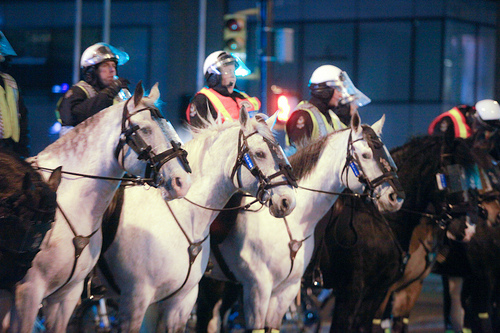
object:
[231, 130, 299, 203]
bridle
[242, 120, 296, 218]
horse face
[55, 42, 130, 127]
officer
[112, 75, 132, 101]
water bottle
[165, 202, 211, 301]
harness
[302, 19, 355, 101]
window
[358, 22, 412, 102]
window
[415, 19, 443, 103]
window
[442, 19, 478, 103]
window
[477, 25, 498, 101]
window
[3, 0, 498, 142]
building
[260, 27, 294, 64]
box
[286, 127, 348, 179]
brown mane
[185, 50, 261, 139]
officer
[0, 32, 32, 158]
officer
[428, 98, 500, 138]
officer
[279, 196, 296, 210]
nose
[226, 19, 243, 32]
light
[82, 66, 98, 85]
head set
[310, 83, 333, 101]
head set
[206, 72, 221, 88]
head set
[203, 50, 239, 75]
helmet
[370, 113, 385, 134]
ear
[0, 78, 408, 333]
three horses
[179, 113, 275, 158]
manes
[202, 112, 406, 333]
horse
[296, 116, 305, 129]
badge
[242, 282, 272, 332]
leg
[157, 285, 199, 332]
leg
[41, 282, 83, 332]
leg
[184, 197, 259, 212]
rope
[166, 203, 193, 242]
rope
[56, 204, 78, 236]
rope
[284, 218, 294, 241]
rope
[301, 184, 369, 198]
rope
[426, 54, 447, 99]
wall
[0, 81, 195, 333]
horses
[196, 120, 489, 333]
horses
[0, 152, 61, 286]
horses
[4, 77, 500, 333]
row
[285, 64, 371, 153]
officer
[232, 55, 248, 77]
light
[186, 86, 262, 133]
vest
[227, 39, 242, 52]
light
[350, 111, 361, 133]
ear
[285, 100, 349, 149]
vest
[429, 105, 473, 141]
safety jacket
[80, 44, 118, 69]
helmet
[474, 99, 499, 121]
helmet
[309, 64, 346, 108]
head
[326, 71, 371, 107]
helmet shield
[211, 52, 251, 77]
helmet shield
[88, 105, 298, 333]
horse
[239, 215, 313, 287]
chest